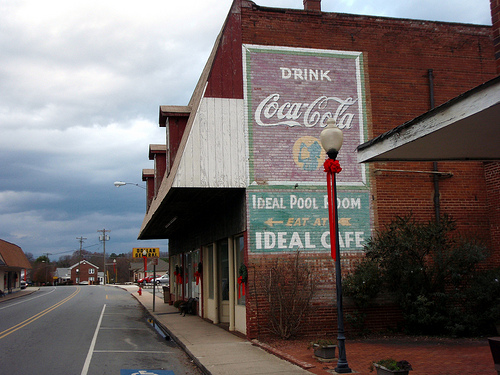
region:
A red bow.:
[321, 154, 343, 259]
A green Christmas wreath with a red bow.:
[232, 266, 252, 296]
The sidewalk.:
[110, 277, 312, 373]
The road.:
[3, 281, 205, 373]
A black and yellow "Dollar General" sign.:
[131, 246, 161, 262]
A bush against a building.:
[347, 212, 499, 332]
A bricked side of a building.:
[244, 79, 498, 339]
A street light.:
[314, 115, 365, 373]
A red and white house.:
[50, 258, 102, 284]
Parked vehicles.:
[136, 271, 171, 289]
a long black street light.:
[301, 112, 368, 373]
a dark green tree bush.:
[334, 198, 498, 353]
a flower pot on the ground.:
[367, 351, 416, 373]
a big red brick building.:
[136, 1, 496, 343]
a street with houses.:
[42, 255, 122, 293]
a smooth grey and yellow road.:
[17, 277, 97, 356]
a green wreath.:
[230, 260, 257, 308]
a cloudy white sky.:
[4, 1, 140, 160]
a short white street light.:
[107, 171, 144, 198]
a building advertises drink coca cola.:
[229, 21, 408, 261]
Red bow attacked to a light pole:
[315, 158, 355, 265]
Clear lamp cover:
[305, 105, 350, 155]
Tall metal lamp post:
[301, 112, 358, 371]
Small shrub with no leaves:
[260, 247, 316, 345]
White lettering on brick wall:
[273, 59, 337, 86]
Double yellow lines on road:
[11, 291, 57, 352]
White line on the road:
[80, 300, 120, 370]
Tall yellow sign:
[115, 233, 165, 265]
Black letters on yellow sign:
[130, 243, 162, 260]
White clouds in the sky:
[30, 91, 113, 230]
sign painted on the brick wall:
[243, 46, 383, 256]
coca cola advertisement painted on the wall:
[241, 45, 380, 256]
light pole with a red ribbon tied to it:
[315, 128, 351, 373]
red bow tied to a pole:
[324, 158, 339, 260]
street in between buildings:
[4, 283, 204, 372]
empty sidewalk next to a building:
[121, 282, 308, 373]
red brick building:
[140, 2, 497, 335]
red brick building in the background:
[54, 260, 101, 285]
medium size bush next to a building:
[342, 213, 497, 335]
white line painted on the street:
[82, 298, 111, 373]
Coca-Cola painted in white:
[250, 87, 358, 140]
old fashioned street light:
[311, 116, 356, 373]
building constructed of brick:
[378, 180, 420, 212]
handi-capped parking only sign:
[113, 364, 171, 374]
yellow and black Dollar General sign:
[131, 244, 164, 261]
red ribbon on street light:
[321, 157, 347, 263]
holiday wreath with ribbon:
[235, 262, 250, 304]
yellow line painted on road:
[0, 275, 90, 363]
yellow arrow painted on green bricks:
[261, 215, 288, 230]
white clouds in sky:
[9, 134, 93, 224]